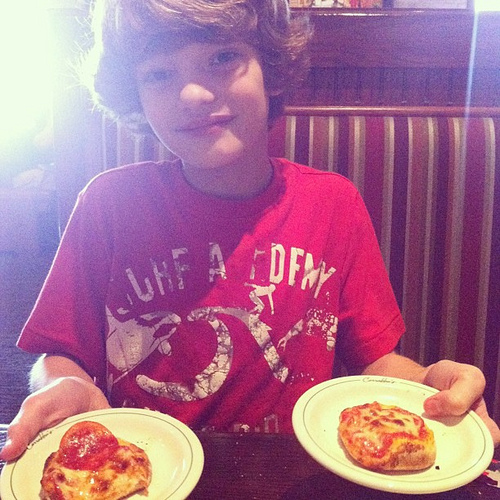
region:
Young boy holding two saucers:
[2, 0, 492, 430]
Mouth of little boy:
[163, 106, 242, 140]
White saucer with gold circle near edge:
[290, 372, 491, 492]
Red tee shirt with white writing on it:
[8, 155, 408, 451]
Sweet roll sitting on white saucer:
[336, 400, 436, 473]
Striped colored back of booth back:
[115, 98, 495, 378]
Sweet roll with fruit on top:
[37, 415, 162, 495]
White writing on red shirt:
[100, 241, 335, 297]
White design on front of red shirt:
[97, 282, 352, 398]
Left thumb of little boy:
[420, 368, 488, 418]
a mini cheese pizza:
[339, 400, 439, 474]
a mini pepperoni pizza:
[42, 420, 150, 498]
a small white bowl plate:
[0, 405, 207, 497]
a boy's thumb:
[418, 386, 479, 418]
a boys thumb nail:
[425, 400, 445, 418]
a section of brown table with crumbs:
[203, 435, 293, 498]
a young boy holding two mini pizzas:
[1, 2, 498, 499]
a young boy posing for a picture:
[0, 2, 499, 499]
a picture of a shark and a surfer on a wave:
[98, 239, 333, 388]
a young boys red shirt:
[11, 163, 407, 436]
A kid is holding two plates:
[5, 8, 492, 495]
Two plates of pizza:
[16, 380, 496, 496]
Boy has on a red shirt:
[0, 2, 478, 477]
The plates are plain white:
[3, 378, 490, 498]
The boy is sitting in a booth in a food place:
[6, 36, 494, 496]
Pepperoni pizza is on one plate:
[11, 390, 184, 497]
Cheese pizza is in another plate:
[315, 382, 466, 489]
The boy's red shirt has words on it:
[0, 6, 490, 491]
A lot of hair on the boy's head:
[83, 5, 303, 141]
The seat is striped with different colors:
[56, 85, 498, 431]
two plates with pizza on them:
[19, 380, 481, 495]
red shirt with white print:
[26, 165, 399, 447]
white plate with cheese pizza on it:
[283, 351, 475, 492]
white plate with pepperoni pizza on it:
[7, 403, 213, 498]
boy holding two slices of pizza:
[27, 6, 486, 488]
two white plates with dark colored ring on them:
[16, 369, 498, 481]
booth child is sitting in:
[60, 112, 495, 434]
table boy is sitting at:
[13, 413, 488, 498]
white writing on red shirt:
[109, 230, 338, 427]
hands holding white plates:
[8, 364, 479, 474]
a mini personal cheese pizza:
[340, 395, 438, 477]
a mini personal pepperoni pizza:
[33, 418, 153, 498]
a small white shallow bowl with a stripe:
[1, 406, 205, 496]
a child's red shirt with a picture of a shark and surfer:
[16, 160, 410, 407]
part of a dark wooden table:
[206, 433, 297, 498]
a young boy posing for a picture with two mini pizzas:
[1, 0, 498, 498]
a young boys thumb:
[421, 383, 483, 417]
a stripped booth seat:
[278, 100, 498, 338]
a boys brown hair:
[88, 1, 314, 109]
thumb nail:
[426, 402, 438, 417]